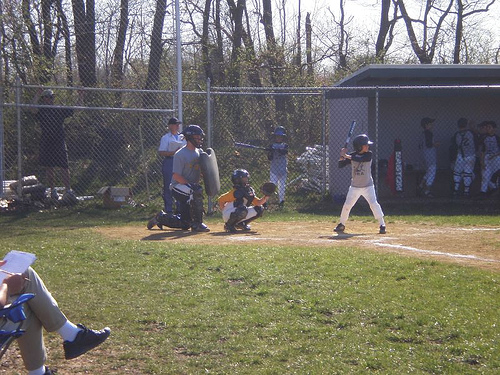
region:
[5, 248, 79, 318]
the person is holding the paper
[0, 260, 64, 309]
the person is holding a pen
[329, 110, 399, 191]
the kid is holding a bat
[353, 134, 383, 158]
the bat is black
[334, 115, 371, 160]
the kid is wearing a helmet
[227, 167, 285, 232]
the player is wearing a glove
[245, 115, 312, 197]
the kid is behind the fence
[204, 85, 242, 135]
the fence is gray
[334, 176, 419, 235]
the pants are white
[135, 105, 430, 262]
baseball game in progress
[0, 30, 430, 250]
fence behind players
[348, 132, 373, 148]
batter wearing a helmet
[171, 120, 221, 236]
man holding a black protective shield-like item in front of him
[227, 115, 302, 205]
child holding bat and standing behind fence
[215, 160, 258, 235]
catcher holding his right arm behind him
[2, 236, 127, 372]
person sitting in chair is partially visible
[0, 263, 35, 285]
person holding writing implement in their right hand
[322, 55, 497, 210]
partially open structure behind fence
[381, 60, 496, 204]
players standing within structure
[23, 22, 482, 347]
baseball game in progress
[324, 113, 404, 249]
boy in batting stance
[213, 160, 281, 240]
catcher with arm behind back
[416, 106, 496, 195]
baseball players in dugout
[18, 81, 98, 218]
person watching game outside fence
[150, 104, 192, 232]
umpire standing behind catcher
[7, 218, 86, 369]
person sitting in chair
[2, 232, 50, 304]
person holding paper and pencil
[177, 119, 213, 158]
man wearing safety helmet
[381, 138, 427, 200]
baseball equipment in dugout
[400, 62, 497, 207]
Boys in baseball uniforms standing in the dugout.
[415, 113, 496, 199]
Boys wearing blue and white uniforms in the dugout.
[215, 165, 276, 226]
Boy squatting with glove on right hand.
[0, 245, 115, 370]
Coach sitting in chair.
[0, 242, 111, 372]
Man sitting in a chair with pencil and paper in hands.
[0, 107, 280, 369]
Man sitting on a blue chair.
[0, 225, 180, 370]
Man sitting blue chair on a baseball field.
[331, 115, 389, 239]
Boy holding a blue bat and helmet.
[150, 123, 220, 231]
Umpire kneeling on the ground.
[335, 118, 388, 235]
Young batter preparing to hit the ball.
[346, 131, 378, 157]
helmet on a persons head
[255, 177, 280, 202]
glove on a persons hand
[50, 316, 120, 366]
black shoe on a foot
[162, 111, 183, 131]
hat on a persons head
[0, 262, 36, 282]
pencil in a persons hand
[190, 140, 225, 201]
chest protector on an umpire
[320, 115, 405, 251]
baseball batter at home plate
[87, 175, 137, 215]
cardboard box on the ground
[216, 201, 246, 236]
shin guard on a catcher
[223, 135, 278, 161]
baseball bat in a persons hand